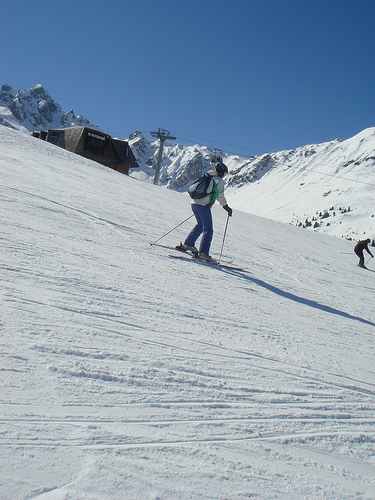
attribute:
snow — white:
[11, 146, 375, 494]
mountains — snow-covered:
[2, 85, 264, 187]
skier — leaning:
[185, 159, 233, 267]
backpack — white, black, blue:
[189, 170, 212, 202]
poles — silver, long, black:
[147, 207, 229, 268]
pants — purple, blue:
[185, 199, 209, 255]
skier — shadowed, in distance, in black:
[349, 236, 371, 272]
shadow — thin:
[209, 258, 373, 327]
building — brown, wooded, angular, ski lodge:
[38, 129, 140, 180]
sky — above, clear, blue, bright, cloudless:
[7, 3, 374, 156]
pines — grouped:
[292, 202, 354, 226]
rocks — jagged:
[5, 80, 88, 129]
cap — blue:
[217, 162, 227, 174]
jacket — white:
[188, 168, 226, 204]